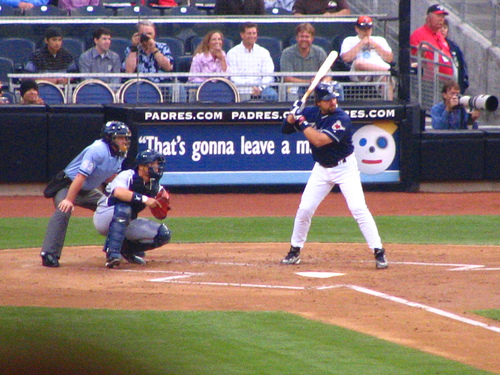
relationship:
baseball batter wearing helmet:
[278, 48, 390, 272] [313, 82, 339, 102]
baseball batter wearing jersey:
[278, 48, 390, 272] [297, 105, 353, 166]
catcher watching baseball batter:
[89, 148, 178, 271] [278, 48, 390, 272]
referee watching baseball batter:
[35, 118, 133, 268] [278, 48, 390, 272]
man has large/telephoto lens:
[429, 80, 481, 130] [459, 94, 498, 110]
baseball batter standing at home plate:
[278, 48, 390, 272] [295, 271, 347, 279]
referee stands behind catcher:
[35, 118, 133, 268] [89, 148, 178, 271]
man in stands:
[429, 80, 481, 130] [3, 0, 412, 180]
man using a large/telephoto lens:
[429, 80, 485, 131] [459, 90, 485, 110]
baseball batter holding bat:
[278, 48, 390, 272] [288, 47, 341, 118]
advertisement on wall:
[129, 110, 399, 186] [1, 100, 419, 190]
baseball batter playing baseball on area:
[278, 48, 390, 272] [0, 302, 500, 375]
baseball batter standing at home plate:
[278, 48, 390, 272] [290, 268, 346, 280]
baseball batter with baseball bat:
[278, 48, 390, 272] [289, 50, 338, 115]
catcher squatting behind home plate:
[89, 148, 178, 271] [292, 267, 346, 282]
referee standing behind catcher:
[35, 118, 133, 268] [89, 148, 178, 271]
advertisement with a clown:
[129, 110, 399, 186] [350, 122, 396, 175]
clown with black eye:
[350, 122, 396, 175] [375, 134, 388, 150]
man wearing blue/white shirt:
[121, 19, 173, 83] [123, 40, 174, 74]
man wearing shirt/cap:
[410, 2, 458, 95] [423, 1, 449, 18]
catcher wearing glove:
[89, 148, 178, 271] [150, 196, 172, 220]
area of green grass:
[5, 304, 318, 371] [129, 327, 204, 372]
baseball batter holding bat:
[278, 48, 390, 272] [282, 49, 341, 115]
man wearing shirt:
[410, 2, 458, 95] [407, 21, 455, 78]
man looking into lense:
[429, 80, 481, 130] [453, 92, 499, 114]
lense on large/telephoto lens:
[453, 92, 499, 114] [459, 94, 498, 110]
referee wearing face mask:
[35, 118, 133, 268] [108, 128, 137, 153]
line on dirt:
[341, 281, 499, 332] [0, 243, 500, 368]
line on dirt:
[167, 272, 338, 286] [0, 243, 500, 368]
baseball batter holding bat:
[278, 48, 390, 272] [287, 46, 343, 110]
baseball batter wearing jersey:
[278, 48, 390, 272] [281, 105, 355, 164]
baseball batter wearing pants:
[278, 48, 390, 272] [282, 164, 383, 253]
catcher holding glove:
[94, 154, 171, 268] [146, 191, 173, 218]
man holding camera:
[121, 19, 173, 83] [139, 32, 148, 42]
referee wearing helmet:
[35, 118, 133, 268] [99, 116, 131, 138]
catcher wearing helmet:
[89, 148, 178, 271] [133, 147, 156, 161]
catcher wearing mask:
[89, 148, 178, 271] [143, 155, 165, 177]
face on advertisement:
[351, 118, 401, 178] [129, 110, 399, 186]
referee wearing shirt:
[35, 118, 133, 268] [61, 135, 123, 190]